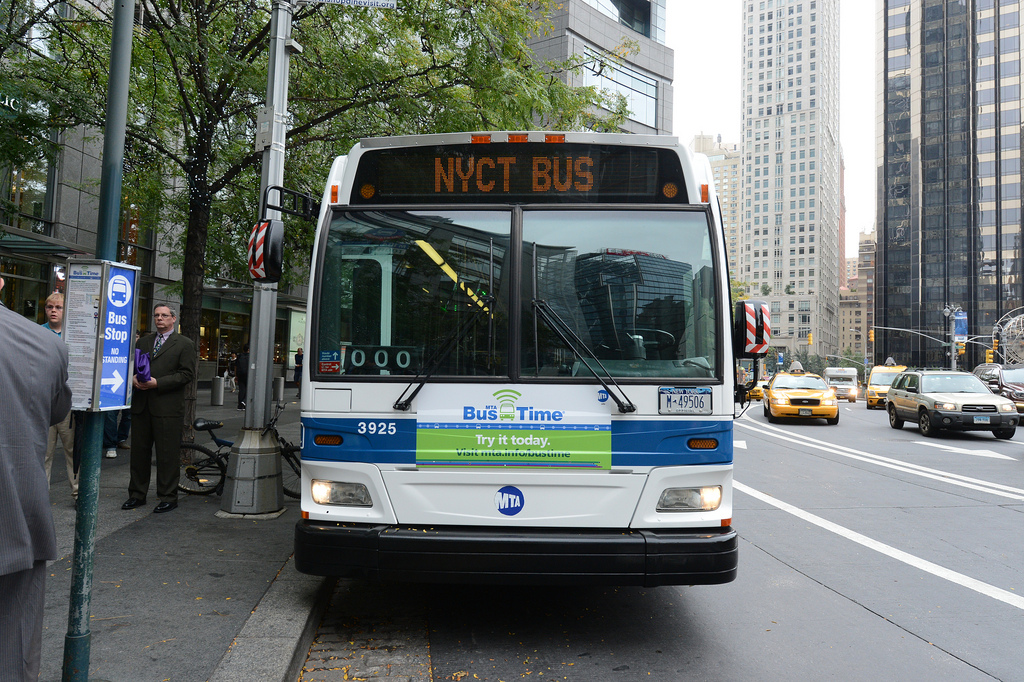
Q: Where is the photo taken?
A: At a bus stop.